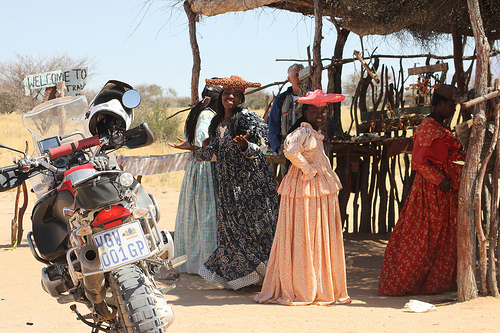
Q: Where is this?
A: This is at the road.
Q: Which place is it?
A: It is a road.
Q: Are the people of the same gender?
A: Yes, all the people are female.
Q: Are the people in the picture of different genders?
A: No, all the people are female.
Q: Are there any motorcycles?
A: Yes, there is a motorcycle.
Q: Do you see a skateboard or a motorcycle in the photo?
A: Yes, there is a motorcycle.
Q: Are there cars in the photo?
A: No, there are no cars.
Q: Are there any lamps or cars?
A: No, there are no cars or lamps.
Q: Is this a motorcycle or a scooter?
A: This is a motorcycle.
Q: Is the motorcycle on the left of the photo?
A: Yes, the motorcycle is on the left of the image.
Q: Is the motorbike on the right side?
A: No, the motorbike is on the left of the image.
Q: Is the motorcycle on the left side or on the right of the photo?
A: The motorcycle is on the left of the image.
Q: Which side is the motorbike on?
A: The motorbike is on the left of the image.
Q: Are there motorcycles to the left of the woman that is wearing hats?
A: Yes, there is a motorcycle to the left of the woman.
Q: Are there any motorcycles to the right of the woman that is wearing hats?
A: No, the motorcycle is to the left of the woman.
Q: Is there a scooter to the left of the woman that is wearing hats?
A: No, there is a motorcycle to the left of the woman.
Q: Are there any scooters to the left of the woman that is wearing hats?
A: No, there is a motorcycle to the left of the woman.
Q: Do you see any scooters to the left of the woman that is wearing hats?
A: No, there is a motorcycle to the left of the woman.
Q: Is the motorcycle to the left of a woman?
A: Yes, the motorcycle is to the left of a woman.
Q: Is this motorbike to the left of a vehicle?
A: No, the motorbike is to the left of a woman.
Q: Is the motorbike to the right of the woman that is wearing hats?
A: No, the motorbike is to the left of the woman.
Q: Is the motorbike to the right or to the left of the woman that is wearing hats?
A: The motorbike is to the left of the woman.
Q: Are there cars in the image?
A: No, there are no cars.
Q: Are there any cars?
A: No, there are no cars.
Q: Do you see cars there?
A: No, there are no cars.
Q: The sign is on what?
A: The sign is on the post.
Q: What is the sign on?
A: The sign is on the post.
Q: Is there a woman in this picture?
A: Yes, there is a woman.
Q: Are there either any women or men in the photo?
A: Yes, there is a woman.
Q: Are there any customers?
A: No, there are no customers.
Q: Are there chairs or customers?
A: No, there are no customers or chairs.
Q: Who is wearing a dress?
A: The woman is wearing a dress.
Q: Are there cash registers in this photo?
A: No, there are no cash registers.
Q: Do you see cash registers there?
A: No, there are no cash registers.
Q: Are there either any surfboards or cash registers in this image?
A: No, there are no cash registers or surfboards.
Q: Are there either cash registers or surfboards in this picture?
A: No, there are no cash registers or surfboards.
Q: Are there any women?
A: Yes, there is a woman.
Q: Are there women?
A: Yes, there is a woman.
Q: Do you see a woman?
A: Yes, there is a woman.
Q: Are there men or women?
A: Yes, there is a woman.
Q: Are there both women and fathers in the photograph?
A: No, there is a woman but no fathers.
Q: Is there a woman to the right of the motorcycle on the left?
A: Yes, there is a woman to the right of the motorbike.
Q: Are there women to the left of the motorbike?
A: No, the woman is to the right of the motorbike.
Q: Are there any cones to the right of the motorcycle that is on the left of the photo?
A: No, there is a woman to the right of the motorbike.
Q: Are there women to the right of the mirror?
A: Yes, there is a woman to the right of the mirror.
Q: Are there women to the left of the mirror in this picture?
A: No, the woman is to the right of the mirror.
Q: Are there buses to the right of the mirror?
A: No, there is a woman to the right of the mirror.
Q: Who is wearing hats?
A: The woman is wearing hats.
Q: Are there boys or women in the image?
A: Yes, there is a woman.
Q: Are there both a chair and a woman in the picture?
A: No, there is a woman but no chairs.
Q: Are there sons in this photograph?
A: No, there are no sons.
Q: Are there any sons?
A: No, there are no sons.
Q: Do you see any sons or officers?
A: No, there are no sons or officers.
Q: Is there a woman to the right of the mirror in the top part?
A: Yes, there is a woman to the right of the mirror.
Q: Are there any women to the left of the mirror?
A: No, the woman is to the right of the mirror.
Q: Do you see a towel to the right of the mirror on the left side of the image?
A: No, there is a woman to the right of the mirror.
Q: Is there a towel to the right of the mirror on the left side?
A: No, there is a woman to the right of the mirror.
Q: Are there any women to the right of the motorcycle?
A: Yes, there is a woman to the right of the motorcycle.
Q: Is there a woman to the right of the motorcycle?
A: Yes, there is a woman to the right of the motorcycle.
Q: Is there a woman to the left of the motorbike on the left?
A: No, the woman is to the right of the motorcycle.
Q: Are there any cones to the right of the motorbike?
A: No, there is a woman to the right of the motorbike.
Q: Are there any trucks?
A: No, there are no trucks.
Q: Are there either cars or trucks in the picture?
A: No, there are no trucks or cars.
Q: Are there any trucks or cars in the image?
A: No, there are no trucks or cars.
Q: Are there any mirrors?
A: Yes, there is a mirror.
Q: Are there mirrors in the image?
A: Yes, there is a mirror.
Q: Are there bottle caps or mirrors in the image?
A: Yes, there is a mirror.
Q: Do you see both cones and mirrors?
A: No, there is a mirror but no cones.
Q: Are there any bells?
A: No, there are no bells.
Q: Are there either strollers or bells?
A: No, there are no bells or strollers.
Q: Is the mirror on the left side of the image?
A: Yes, the mirror is on the left of the image.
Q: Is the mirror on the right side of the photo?
A: No, the mirror is on the left of the image.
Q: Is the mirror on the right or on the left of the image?
A: The mirror is on the left of the image.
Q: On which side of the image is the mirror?
A: The mirror is on the left of the image.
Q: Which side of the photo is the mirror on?
A: The mirror is on the left of the image.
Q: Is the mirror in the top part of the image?
A: Yes, the mirror is in the top of the image.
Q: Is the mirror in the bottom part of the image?
A: No, the mirror is in the top of the image.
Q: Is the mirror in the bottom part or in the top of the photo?
A: The mirror is in the top of the image.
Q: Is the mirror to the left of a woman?
A: Yes, the mirror is to the left of a woman.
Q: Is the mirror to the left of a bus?
A: No, the mirror is to the left of a woman.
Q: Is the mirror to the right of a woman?
A: No, the mirror is to the left of a woman.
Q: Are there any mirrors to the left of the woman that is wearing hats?
A: Yes, there is a mirror to the left of the woman.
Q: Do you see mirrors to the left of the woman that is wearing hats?
A: Yes, there is a mirror to the left of the woman.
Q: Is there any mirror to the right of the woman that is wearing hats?
A: No, the mirror is to the left of the woman.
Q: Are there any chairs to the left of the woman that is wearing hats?
A: No, there is a mirror to the left of the woman.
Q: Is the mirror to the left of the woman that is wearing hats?
A: Yes, the mirror is to the left of the woman.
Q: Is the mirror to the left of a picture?
A: No, the mirror is to the left of the woman.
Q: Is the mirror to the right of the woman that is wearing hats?
A: No, the mirror is to the left of the woman.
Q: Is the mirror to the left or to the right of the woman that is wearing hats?
A: The mirror is to the left of the woman.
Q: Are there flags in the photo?
A: No, there are no flags.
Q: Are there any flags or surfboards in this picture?
A: No, there are no flags or surfboards.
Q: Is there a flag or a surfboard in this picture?
A: No, there are no flags or surfboards.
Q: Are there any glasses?
A: No, there are no glasses.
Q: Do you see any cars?
A: No, there are no cars.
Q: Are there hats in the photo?
A: Yes, there is a hat.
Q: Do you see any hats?
A: Yes, there is a hat.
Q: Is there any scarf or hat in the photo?
A: Yes, there is a hat.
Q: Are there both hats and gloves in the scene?
A: No, there is a hat but no gloves.